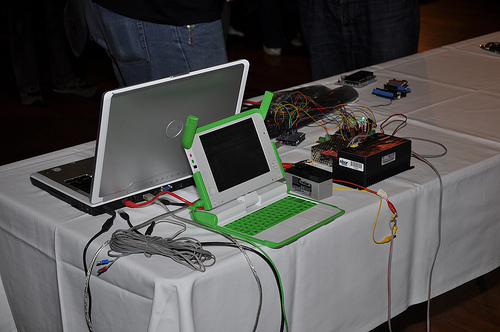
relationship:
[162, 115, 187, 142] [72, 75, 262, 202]
logo on laptop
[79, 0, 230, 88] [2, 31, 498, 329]
people standing by table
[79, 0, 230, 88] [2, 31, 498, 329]
people by table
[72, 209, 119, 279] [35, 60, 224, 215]
power cord on laptop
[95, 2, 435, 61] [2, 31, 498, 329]
people next to table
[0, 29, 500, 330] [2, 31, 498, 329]
table cloth on table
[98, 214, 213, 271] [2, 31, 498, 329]
cord on table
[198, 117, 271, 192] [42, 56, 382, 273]
screen on laptop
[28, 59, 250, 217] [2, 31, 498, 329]
computer on table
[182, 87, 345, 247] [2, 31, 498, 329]
laptop on table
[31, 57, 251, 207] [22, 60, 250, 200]
trimmings on laptop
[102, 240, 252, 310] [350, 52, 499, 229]
table cloth on table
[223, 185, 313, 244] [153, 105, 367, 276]
keyboard on laptop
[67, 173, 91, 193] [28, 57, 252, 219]
keys on computer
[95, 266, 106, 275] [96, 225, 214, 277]
end on cable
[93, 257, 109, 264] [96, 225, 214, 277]
end on cable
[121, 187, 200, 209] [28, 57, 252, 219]
cable on computer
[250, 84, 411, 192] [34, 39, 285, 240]
parts of laptop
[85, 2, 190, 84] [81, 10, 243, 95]
jeans on person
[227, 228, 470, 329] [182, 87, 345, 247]
wires on laptop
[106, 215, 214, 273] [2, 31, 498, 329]
wires on table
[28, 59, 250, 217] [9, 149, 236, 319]
computer on table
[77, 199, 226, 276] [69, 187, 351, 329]
bundle of wires